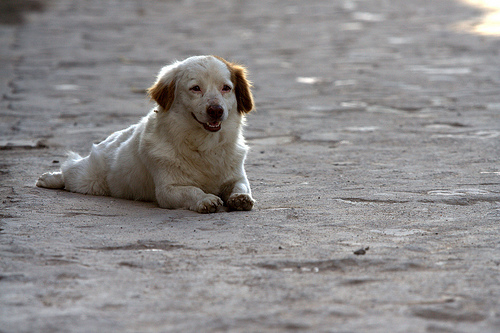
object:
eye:
[221, 84, 232, 92]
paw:
[196, 195, 224, 213]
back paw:
[35, 172, 64, 189]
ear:
[213, 57, 253, 114]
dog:
[35, 55, 255, 215]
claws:
[201, 205, 206, 211]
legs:
[225, 179, 255, 212]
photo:
[0, 0, 500, 333]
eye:
[190, 85, 202, 92]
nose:
[206, 106, 224, 118]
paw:
[228, 193, 255, 211]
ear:
[147, 60, 182, 112]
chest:
[185, 145, 234, 183]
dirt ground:
[0, 0, 500, 333]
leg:
[151, 173, 224, 214]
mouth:
[203, 120, 223, 132]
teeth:
[206, 121, 221, 127]